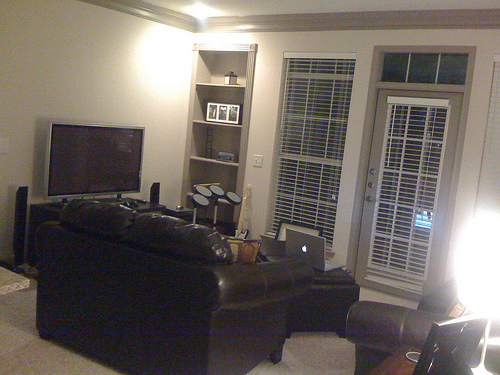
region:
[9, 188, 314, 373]
room has a loveseat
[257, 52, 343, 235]
windows have blinds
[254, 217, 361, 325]
laptop on the ottoman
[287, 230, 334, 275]
the laptop is apple brand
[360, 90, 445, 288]
the door has a mini blind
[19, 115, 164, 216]
Large flat screen tv on stand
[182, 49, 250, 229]
room has built in shelving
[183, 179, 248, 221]
room has a set of digital drums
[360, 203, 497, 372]
lamp on a stand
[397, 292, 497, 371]
picture frame by the lamp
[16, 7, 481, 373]
Picture of a living room.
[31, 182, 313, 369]
A black leather couch.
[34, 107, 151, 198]
Large flat screen tv.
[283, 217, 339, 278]
An open laptop.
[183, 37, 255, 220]
Shelving made into the wall.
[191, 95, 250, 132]
Picture frame with three pictures.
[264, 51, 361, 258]
Long window beside door.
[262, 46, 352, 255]
White blinds on window.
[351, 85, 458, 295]
A door with glass panes.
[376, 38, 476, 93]
Three small windows over door.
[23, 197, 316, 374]
Black leather love seat.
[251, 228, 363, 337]
A black leather ottoman.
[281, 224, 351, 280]
Laptop computer sitting on ottoman.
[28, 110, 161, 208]
Television sitting on stand.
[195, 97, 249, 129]
Picture sitting on shelf.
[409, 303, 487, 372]
Picture sitting on end table.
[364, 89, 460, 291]
Mini blinds on door.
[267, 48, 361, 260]
Mini blinds on window.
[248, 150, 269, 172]
Light switch on wall by window.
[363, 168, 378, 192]
Two locks on door.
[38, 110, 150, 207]
television on a table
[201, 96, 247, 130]
picture frame on a shelf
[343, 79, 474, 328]
door in a room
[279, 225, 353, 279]
laptop computer on furniture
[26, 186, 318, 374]
couch on the floor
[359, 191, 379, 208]
door handle on a door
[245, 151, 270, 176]
light switches on a wall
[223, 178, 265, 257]
guitar against a wall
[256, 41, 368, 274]
window on a wall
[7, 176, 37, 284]
speaker on the floor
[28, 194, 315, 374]
leather love seat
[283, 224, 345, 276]
Apple brand laptop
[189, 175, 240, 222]
drums on stand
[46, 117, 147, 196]
wide screen television on tv stand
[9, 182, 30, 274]
speaker on left of tv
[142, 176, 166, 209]
speaker on right of tv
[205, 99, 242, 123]
three pane frame on shelf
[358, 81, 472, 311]
window paned door with blinds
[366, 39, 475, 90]
transom over door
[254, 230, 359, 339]
ottoman with laptop on top